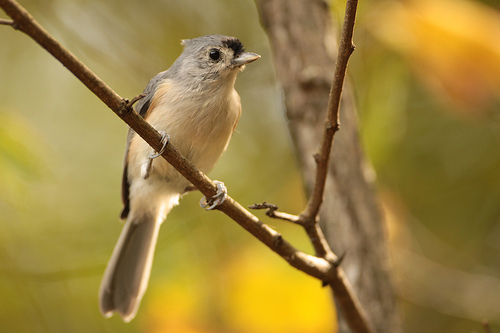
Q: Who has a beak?
A: Bird.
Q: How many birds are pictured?
A: One.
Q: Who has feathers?
A: The bird.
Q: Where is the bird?
A: On tree branch.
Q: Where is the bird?
A: On a tree branch.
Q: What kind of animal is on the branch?
A: A bird.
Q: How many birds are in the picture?
A: 1.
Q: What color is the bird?
A: White and gray.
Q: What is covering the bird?
A: Feathers.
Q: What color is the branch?
A: Brown.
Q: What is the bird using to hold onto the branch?
A: Claws.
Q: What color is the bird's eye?
A: Black.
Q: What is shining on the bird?
A: The sun.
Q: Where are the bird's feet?
A: Wrapped around tree branch.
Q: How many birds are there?
A: One.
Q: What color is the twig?
A: Brown.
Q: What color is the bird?
A: Gray and white.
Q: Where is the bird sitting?
A: On a twig.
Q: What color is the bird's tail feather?
A: Gray.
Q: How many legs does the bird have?
A: Two.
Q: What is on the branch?
A: Bird.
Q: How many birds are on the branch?
A: 1.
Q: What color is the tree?
A: Brown.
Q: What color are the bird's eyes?
A: Black.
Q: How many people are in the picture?
A: None.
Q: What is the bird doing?
A: Sitting.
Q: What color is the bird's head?
A: Gray.